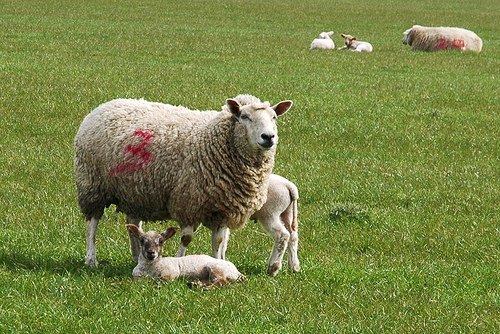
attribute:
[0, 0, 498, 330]
green grass — trimmed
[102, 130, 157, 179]
letter — red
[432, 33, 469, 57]
letter — red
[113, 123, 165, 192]
letter — red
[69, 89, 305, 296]
sheep — clean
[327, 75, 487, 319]
clean grass — neat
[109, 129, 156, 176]
letter — red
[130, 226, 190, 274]
baby — lamb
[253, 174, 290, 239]
baby — lamb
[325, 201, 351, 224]
letter — red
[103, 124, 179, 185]
letter — red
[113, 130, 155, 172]
letter — red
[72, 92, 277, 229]
coat — long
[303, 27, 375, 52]
lambs — white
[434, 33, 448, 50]
number — red, painted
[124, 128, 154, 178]
number — red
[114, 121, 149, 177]
marking — red, identification